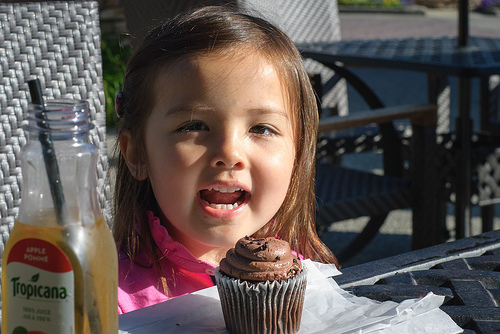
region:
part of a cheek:
[266, 147, 290, 189]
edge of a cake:
[256, 289, 288, 299]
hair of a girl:
[290, 198, 310, 235]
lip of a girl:
[201, 201, 237, 242]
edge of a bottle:
[78, 237, 120, 277]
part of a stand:
[405, 187, 442, 229]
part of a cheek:
[166, 165, 193, 181]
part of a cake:
[248, 262, 293, 328]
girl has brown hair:
[134, 9, 391, 228]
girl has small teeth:
[186, 163, 264, 210]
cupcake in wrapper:
[215, 238, 321, 325]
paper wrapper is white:
[205, 253, 290, 332]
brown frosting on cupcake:
[221, 233, 318, 310]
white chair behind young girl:
[7, 23, 111, 201]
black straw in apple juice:
[20, 74, 82, 234]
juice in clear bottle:
[32, 115, 127, 322]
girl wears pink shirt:
[100, 203, 202, 332]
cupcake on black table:
[185, 250, 332, 332]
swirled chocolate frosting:
[218, 235, 300, 276]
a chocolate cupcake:
[204, 265, 307, 332]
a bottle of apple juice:
[5, 91, 121, 329]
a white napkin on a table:
[118, 256, 463, 332]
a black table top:
[334, 227, 498, 332]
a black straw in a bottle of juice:
[26, 72, 85, 234]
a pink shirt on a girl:
[110, 208, 231, 318]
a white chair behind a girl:
[0, 2, 114, 269]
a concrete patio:
[306, 134, 496, 268]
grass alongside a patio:
[102, 20, 142, 137]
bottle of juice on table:
[5, 75, 163, 322]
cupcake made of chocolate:
[190, 222, 338, 327]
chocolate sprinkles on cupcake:
[220, 217, 294, 281]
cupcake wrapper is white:
[205, 261, 340, 331]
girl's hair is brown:
[56, 2, 377, 249]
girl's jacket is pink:
[99, 188, 227, 300]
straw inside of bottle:
[15, 60, 100, 237]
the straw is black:
[20, 65, 82, 237]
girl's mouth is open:
[187, 177, 265, 225]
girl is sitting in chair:
[3, 2, 400, 319]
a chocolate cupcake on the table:
[215, 233, 307, 332]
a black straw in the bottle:
[25, 76, 74, 228]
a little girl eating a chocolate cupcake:
[112, 5, 316, 315]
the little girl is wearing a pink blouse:
[115, 211, 195, 312]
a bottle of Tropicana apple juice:
[1, 98, 118, 332]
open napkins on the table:
[308, 258, 468, 332]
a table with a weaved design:
[440, 226, 497, 333]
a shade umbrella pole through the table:
[454, 1, 474, 236]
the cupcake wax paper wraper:
[212, 269, 308, 332]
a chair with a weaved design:
[315, 96, 432, 261]